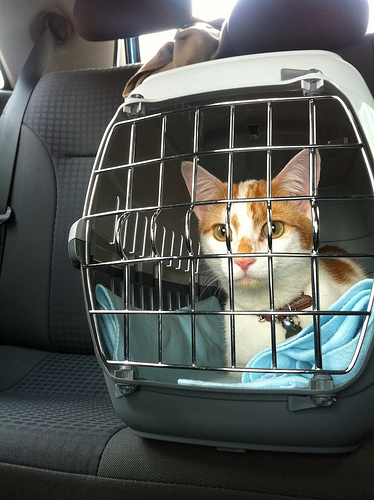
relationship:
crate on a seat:
[102, 90, 349, 376] [40, 408, 371, 495]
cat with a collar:
[178, 146, 368, 380] [246, 294, 310, 331]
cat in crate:
[170, 135, 365, 373] [63, 32, 369, 443]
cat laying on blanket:
[178, 146, 368, 380] [94, 279, 373, 389]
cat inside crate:
[178, 146, 368, 380] [69, 49, 374, 454]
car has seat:
[0, 2, 372, 491] [10, 69, 171, 487]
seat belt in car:
[1, 14, 71, 277] [0, 2, 372, 491]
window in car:
[137, 0, 236, 61] [0, 2, 372, 491]